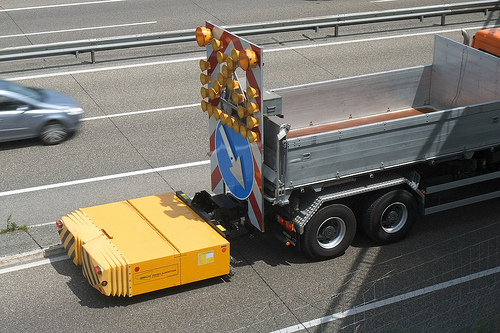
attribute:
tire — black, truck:
[305, 181, 430, 253]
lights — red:
[206, 127, 308, 243]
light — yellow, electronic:
[193, 24, 215, 54]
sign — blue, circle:
[191, 15, 279, 234]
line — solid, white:
[1, 159, 207, 194]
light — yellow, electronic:
[235, 118, 263, 144]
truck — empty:
[135, 30, 493, 276]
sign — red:
[193, 17, 268, 235]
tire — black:
[29, 104, 96, 163]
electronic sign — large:
[56, 191, 231, 303]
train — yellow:
[48, 181, 242, 302]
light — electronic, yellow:
[207, 106, 227, 128]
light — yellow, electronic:
[245, 87, 257, 100]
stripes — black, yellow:
[56, 225, 105, 297]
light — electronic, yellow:
[248, 102, 256, 112]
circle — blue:
[205, 115, 267, 215]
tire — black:
[288, 182, 430, 286]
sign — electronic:
[192, 36, 306, 173]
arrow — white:
[213, 122, 248, 194]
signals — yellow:
[192, 15, 268, 240]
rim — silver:
[313, 211, 343, 251]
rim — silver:
[380, 204, 410, 234]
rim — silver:
[45, 124, 65, 147]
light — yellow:
[193, 28, 255, 153]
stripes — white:
[203, 125, 264, 228]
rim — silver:
[372, 194, 417, 244]